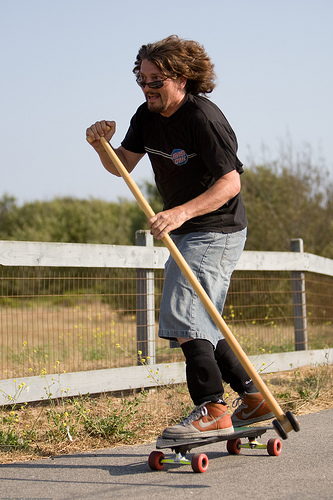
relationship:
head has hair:
[133, 34, 188, 116] [133, 37, 214, 97]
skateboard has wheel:
[149, 423, 281, 472] [268, 438, 282, 456]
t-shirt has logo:
[121, 93, 248, 233] [144, 145, 197, 166]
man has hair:
[88, 37, 277, 439] [133, 37, 214, 97]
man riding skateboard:
[88, 37, 277, 439] [149, 423, 281, 472]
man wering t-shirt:
[88, 37, 277, 439] [121, 93, 248, 233]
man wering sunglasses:
[88, 37, 277, 439] [138, 74, 172, 88]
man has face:
[88, 37, 277, 439] [137, 60, 170, 112]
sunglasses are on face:
[138, 74, 172, 88] [137, 60, 170, 112]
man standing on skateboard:
[88, 37, 277, 439] [149, 423, 281, 472]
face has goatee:
[137, 60, 170, 112] [143, 89, 166, 114]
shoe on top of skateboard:
[165, 403, 234, 439] [149, 423, 281, 472]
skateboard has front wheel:
[149, 423, 281, 472] [189, 450, 208, 472]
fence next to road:
[2, 231, 333, 404] [0, 413, 330, 499]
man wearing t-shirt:
[88, 37, 277, 439] [121, 93, 248, 233]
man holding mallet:
[88, 37, 277, 439] [100, 137, 298, 438]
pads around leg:
[182, 338, 223, 413] [161, 227, 247, 399]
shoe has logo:
[165, 403, 234, 439] [197, 412, 226, 428]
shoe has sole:
[165, 403, 234, 439] [166, 427, 235, 437]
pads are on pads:
[182, 338, 223, 413] [182, 338, 223, 413]